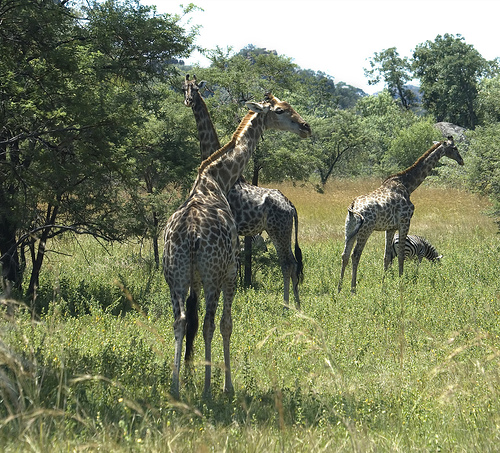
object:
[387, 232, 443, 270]
short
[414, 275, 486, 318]
green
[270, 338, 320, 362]
yellow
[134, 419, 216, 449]
brown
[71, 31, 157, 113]
green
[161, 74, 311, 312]
giraffe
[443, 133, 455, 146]
dark horns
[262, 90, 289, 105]
dark horns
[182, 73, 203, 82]
dark horns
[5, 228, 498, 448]
grass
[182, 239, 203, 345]
tail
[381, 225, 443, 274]
zebra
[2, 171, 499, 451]
grass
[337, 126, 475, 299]
giraffe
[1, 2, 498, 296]
trees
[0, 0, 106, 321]
tree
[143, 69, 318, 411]
animal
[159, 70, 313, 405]
animal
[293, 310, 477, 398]
brown grass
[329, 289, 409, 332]
green grass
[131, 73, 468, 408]
giraffe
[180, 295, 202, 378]
black tail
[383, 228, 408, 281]
legs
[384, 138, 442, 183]
man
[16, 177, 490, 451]
treegrass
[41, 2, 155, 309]
trees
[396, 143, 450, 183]
mane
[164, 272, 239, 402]
legs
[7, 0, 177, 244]
leaves